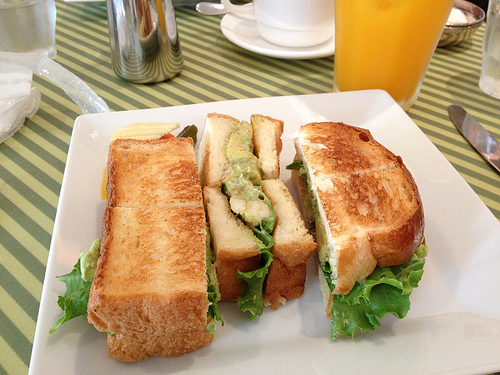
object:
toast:
[88, 134, 214, 363]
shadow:
[79, 361, 145, 373]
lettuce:
[368, 287, 427, 344]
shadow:
[335, 327, 398, 347]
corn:
[109, 119, 178, 140]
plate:
[25, 88, 500, 375]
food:
[105, 120, 386, 314]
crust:
[127, 300, 196, 361]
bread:
[103, 128, 201, 348]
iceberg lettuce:
[65, 255, 108, 327]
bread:
[207, 199, 250, 306]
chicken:
[223, 144, 288, 234]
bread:
[316, 130, 381, 217]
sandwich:
[210, 111, 322, 312]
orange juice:
[359, 24, 409, 84]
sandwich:
[98, 122, 241, 354]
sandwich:
[308, 102, 425, 334]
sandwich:
[138, 133, 439, 300]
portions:
[93, 115, 222, 364]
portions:
[273, 108, 441, 358]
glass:
[346, 3, 403, 63]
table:
[6, 13, 493, 345]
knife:
[445, 88, 498, 168]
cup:
[247, 5, 336, 50]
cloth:
[172, 65, 272, 97]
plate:
[210, 6, 333, 66]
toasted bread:
[115, 142, 194, 192]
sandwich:
[116, 301, 195, 351]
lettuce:
[357, 282, 409, 317]